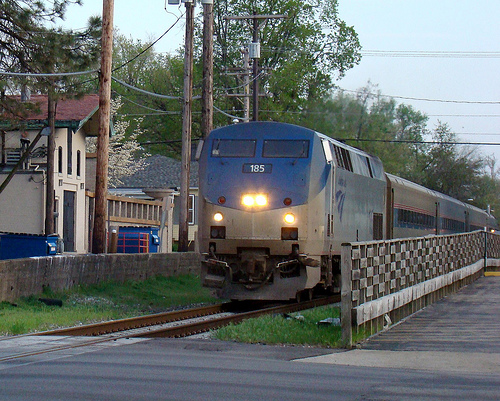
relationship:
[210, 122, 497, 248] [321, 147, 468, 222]
train carrying passengers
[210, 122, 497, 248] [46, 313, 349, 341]
train on tracks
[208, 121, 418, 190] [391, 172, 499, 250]
train pulling cars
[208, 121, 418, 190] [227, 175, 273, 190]
train has lights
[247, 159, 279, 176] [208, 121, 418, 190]
number on train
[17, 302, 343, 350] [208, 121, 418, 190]
grass next to train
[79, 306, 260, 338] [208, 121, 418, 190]
track under train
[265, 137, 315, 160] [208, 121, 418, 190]
window on train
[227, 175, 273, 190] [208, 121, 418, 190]
lights on train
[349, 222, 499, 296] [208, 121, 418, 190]
fence near train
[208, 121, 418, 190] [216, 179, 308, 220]
train has headlight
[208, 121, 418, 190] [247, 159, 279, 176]
train has number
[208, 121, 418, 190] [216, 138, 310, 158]
train has windshield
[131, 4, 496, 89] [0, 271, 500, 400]
sky above floor